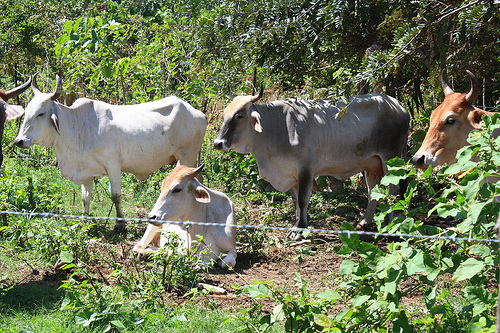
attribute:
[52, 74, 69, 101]
chunks — big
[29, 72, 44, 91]
chunks — big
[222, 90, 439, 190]
cow — gray 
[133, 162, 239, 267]
cow — brown and white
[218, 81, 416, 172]
cow — black, white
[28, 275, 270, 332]
grass — Green 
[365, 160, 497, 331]
leaf — green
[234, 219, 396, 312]
dirt — brown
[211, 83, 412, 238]
cow — black, white, standing, gray 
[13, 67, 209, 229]
bull — standing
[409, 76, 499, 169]
cow — brown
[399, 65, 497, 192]
bull — maroon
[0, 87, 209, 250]
cow — white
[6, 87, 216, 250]
bull — white